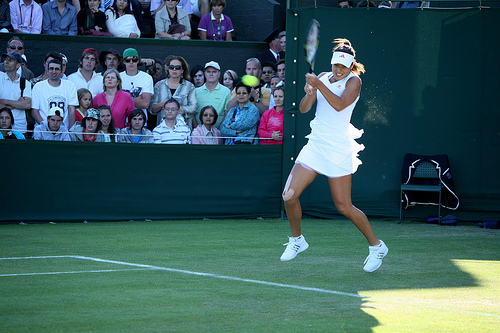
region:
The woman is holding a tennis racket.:
[271, 12, 392, 281]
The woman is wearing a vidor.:
[286, 10, 369, 122]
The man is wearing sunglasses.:
[116, 43, 144, 95]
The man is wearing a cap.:
[195, 56, 227, 100]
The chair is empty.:
[388, 138, 465, 235]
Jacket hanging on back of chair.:
[389, 142, 464, 229]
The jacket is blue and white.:
[396, 141, 466, 229]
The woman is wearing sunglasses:
[156, 50, 193, 102]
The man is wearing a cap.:
[65, 104, 108, 143]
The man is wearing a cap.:
[67, 41, 103, 83]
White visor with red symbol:
[330, 47, 355, 69]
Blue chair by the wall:
[401, 155, 445, 217]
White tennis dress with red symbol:
[297, 65, 364, 181]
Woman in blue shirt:
[220, 82, 260, 143]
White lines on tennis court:
[20, 249, 152, 280]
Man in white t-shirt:
[25, 60, 79, 114]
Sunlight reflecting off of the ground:
[350, 254, 497, 330]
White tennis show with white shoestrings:
[276, 233, 311, 265]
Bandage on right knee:
[280, 172, 297, 205]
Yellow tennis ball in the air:
[238, 73, 262, 87]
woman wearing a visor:
[275, 25, 415, 290]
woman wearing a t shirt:
[260, 30, 400, 300]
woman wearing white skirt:
[245, 5, 410, 300]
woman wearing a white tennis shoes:
[260, 10, 400, 280]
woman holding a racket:
[255, 10, 385, 300]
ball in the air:
[240, 55, 265, 110]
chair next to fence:
[385, 136, 470, 231]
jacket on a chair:
[385, 132, 460, 227]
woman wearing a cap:
[120, 40, 150, 91]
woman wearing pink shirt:
[95, 66, 127, 111]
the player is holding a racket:
[271, 17, 374, 211]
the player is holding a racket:
[281, 23, 384, 187]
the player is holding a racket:
[273, 15, 383, 220]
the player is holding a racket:
[276, 11, 396, 251]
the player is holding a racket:
[271, 13, 377, 230]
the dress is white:
[288, 65, 380, 217]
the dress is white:
[286, 44, 383, 212]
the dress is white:
[297, 72, 376, 194]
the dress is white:
[307, 72, 382, 216]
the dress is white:
[278, 42, 373, 189]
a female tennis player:
[282, 18, 389, 273]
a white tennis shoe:
[279, 236, 307, 261]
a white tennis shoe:
[363, 237, 389, 274]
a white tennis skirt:
[292, 137, 365, 178]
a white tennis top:
[305, 73, 360, 143]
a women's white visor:
[330, 50, 353, 68]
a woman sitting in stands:
[189, 103, 222, 144]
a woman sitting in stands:
[219, 83, 256, 143]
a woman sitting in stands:
[98, 103, 116, 131]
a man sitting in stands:
[116, 108, 153, 143]